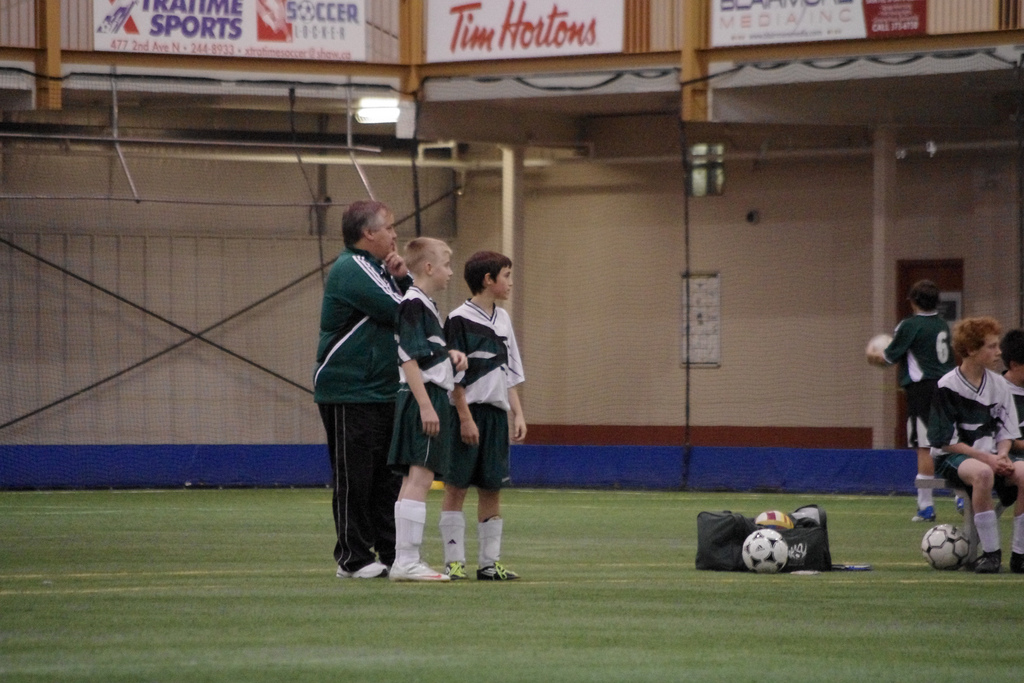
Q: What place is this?
A: It is a field.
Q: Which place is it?
A: It is a field.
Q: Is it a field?
A: Yes, it is a field.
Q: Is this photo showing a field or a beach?
A: It is showing a field.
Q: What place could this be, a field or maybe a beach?
A: It is a field.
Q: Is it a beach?
A: No, it is a field.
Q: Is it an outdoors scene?
A: Yes, it is outdoors.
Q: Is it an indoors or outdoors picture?
A: It is outdoors.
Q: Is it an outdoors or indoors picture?
A: It is outdoors.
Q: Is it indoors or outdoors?
A: It is outdoors.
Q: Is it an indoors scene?
A: No, it is outdoors.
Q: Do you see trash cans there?
A: No, there are no trash cans.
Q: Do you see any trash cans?
A: No, there are no trash cans.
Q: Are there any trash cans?
A: No, there are no trash cans.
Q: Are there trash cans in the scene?
A: No, there are no trash cans.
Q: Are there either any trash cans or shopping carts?
A: No, there are no trash cans or shopping carts.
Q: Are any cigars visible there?
A: No, there are no cigars.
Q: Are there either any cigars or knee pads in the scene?
A: No, there are no cigars or knee pads.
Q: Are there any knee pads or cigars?
A: No, there are no cigars or knee pads.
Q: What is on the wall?
A: The poster is on the wall.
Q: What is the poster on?
A: The poster is on the wall.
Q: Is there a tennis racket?
A: No, there are no rackets.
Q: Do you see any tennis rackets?
A: No, there are no tennis rackets.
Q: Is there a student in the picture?
A: No, there are no students.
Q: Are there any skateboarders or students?
A: No, there are no students or skateboarders.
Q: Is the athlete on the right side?
A: Yes, the athlete is on the right of the image.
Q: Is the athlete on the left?
A: No, the athlete is on the right of the image.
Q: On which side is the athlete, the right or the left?
A: The athlete is on the right of the image.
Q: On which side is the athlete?
A: The athlete is on the right of the image.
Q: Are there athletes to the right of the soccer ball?
A: Yes, there is an athlete to the right of the soccer ball.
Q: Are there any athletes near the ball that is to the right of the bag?
A: Yes, there is an athlete near the ball.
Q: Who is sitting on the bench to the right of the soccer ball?
A: The athlete is sitting on the bench.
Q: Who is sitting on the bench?
A: The athlete is sitting on the bench.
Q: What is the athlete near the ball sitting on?
A: The athlete is sitting on the bench.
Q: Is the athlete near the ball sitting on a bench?
A: Yes, the athlete is sitting on a bench.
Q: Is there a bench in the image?
A: Yes, there is a bench.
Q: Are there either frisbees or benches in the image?
A: Yes, there is a bench.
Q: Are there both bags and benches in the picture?
A: Yes, there are both a bench and a bag.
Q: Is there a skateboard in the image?
A: No, there are no skateboards.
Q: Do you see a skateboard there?
A: No, there are no skateboards.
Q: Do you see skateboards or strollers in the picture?
A: No, there are no skateboards or strollers.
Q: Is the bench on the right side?
A: Yes, the bench is on the right of the image.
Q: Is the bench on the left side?
A: No, the bench is on the right of the image.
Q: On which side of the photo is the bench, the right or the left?
A: The bench is on the right of the image.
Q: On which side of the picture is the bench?
A: The bench is on the right of the image.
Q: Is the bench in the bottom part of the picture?
A: Yes, the bench is in the bottom of the image.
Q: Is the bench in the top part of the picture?
A: No, the bench is in the bottom of the image.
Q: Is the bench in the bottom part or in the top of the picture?
A: The bench is in the bottom of the image.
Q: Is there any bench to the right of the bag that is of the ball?
A: Yes, there is a bench to the right of the bag.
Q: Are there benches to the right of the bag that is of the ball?
A: Yes, there is a bench to the right of the bag.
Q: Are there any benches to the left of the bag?
A: No, the bench is to the right of the bag.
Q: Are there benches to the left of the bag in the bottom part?
A: No, the bench is to the right of the bag.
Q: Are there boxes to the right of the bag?
A: No, there is a bench to the right of the bag.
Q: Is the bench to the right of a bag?
A: Yes, the bench is to the right of a bag.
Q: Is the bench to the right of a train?
A: No, the bench is to the right of a bag.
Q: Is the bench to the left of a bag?
A: No, the bench is to the right of a bag.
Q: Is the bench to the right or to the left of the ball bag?
A: The bench is to the right of the bag.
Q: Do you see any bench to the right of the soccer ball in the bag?
A: Yes, there is a bench to the right of the soccer ball.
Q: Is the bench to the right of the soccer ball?
A: Yes, the bench is to the right of the soccer ball.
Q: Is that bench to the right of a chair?
A: No, the bench is to the right of the soccer ball.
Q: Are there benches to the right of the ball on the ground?
A: Yes, there is a bench to the right of the ball.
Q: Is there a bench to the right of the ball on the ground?
A: Yes, there is a bench to the right of the ball.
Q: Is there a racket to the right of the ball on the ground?
A: No, there is a bench to the right of the ball.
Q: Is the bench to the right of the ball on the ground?
A: Yes, the bench is to the right of the ball.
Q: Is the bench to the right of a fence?
A: No, the bench is to the right of the ball.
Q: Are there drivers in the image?
A: No, there are no drivers.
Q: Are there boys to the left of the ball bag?
A: Yes, there is a boy to the left of the bag.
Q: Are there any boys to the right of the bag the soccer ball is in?
A: No, the boy is to the left of the bag.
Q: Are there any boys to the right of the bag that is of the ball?
A: No, the boy is to the left of the bag.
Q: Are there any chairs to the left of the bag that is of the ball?
A: No, there is a boy to the left of the bag.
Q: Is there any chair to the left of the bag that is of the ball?
A: No, there is a boy to the left of the bag.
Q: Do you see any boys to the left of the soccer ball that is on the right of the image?
A: Yes, there is a boy to the left of the soccer ball.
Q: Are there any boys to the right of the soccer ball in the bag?
A: No, the boy is to the left of the soccer ball.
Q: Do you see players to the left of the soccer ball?
A: No, there is a boy to the left of the soccer ball.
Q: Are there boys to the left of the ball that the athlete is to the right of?
A: Yes, there is a boy to the left of the ball.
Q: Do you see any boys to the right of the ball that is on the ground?
A: No, the boy is to the left of the ball.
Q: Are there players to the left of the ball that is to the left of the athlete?
A: No, there is a boy to the left of the ball.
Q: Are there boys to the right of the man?
A: Yes, there is a boy to the right of the man.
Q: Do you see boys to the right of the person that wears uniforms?
A: Yes, there is a boy to the right of the man.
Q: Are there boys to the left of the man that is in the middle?
A: No, the boy is to the right of the man.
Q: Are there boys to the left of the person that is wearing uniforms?
A: No, the boy is to the right of the man.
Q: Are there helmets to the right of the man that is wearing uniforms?
A: No, there is a boy to the right of the man.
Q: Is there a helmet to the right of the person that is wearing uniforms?
A: No, there is a boy to the right of the man.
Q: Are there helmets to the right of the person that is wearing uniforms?
A: No, there is a boy to the right of the man.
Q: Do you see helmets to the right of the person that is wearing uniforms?
A: No, there is a boy to the right of the man.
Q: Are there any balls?
A: Yes, there is a ball.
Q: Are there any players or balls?
A: Yes, there is a ball.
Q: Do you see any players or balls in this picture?
A: Yes, there is a ball.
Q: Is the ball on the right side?
A: Yes, the ball is on the right of the image.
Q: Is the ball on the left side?
A: No, the ball is on the right of the image.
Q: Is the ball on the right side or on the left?
A: The ball is on the right of the image.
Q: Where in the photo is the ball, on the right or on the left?
A: The ball is on the right of the image.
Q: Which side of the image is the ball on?
A: The ball is on the right of the image.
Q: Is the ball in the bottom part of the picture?
A: Yes, the ball is in the bottom of the image.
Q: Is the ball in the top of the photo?
A: No, the ball is in the bottom of the image.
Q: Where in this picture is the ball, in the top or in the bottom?
A: The ball is in the bottom of the image.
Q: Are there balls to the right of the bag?
A: Yes, there is a ball to the right of the bag.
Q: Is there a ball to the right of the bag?
A: Yes, there is a ball to the right of the bag.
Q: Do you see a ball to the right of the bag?
A: Yes, there is a ball to the right of the bag.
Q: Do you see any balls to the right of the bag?
A: Yes, there is a ball to the right of the bag.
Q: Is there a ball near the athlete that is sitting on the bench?
A: Yes, there is a ball near the athlete.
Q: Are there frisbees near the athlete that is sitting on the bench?
A: No, there is a ball near the athlete.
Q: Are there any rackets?
A: No, there are no rackets.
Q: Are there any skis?
A: No, there are no skis.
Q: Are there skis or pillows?
A: No, there are no skis or pillows.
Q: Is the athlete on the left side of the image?
A: No, the athlete is on the right of the image.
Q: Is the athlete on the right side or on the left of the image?
A: The athlete is on the right of the image.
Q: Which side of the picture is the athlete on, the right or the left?
A: The athlete is on the right of the image.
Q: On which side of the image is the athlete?
A: The athlete is on the right of the image.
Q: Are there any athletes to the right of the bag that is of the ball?
A: Yes, there is an athlete to the right of the bag.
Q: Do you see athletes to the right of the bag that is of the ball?
A: Yes, there is an athlete to the right of the bag.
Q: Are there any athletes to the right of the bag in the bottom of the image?
A: Yes, there is an athlete to the right of the bag.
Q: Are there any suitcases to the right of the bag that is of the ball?
A: No, there is an athlete to the right of the bag.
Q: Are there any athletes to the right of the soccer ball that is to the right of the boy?
A: Yes, there is an athlete to the right of the soccer ball.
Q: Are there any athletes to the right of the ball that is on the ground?
A: Yes, there is an athlete to the right of the ball.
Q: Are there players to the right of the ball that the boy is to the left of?
A: No, there is an athlete to the right of the ball.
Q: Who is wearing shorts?
A: The athlete is wearing shorts.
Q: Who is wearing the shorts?
A: The athlete is wearing shorts.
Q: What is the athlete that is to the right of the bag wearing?
A: The athlete is wearing shorts.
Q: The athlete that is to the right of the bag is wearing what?
A: The athlete is wearing shorts.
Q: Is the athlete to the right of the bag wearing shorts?
A: Yes, the athlete is wearing shorts.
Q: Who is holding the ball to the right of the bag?
A: The athlete is holding the ball.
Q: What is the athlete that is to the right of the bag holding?
A: The athlete is holding the ball.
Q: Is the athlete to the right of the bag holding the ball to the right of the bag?
A: Yes, the athlete is holding the ball.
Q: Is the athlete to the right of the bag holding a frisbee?
A: No, the athlete is holding the ball.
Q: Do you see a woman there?
A: No, there are no women.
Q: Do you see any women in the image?
A: No, there are no women.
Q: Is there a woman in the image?
A: No, there are no women.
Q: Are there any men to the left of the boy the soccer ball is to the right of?
A: Yes, there is a man to the left of the boy.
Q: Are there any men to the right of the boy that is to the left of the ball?
A: No, the man is to the left of the boy.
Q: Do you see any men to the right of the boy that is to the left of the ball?
A: No, the man is to the left of the boy.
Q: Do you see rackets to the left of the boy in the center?
A: No, there is a man to the left of the boy.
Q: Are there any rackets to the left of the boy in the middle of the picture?
A: No, there is a man to the left of the boy.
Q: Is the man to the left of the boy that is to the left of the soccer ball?
A: Yes, the man is to the left of the boy.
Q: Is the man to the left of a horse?
A: No, the man is to the left of the boy.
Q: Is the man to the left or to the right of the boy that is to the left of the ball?
A: The man is to the left of the boy.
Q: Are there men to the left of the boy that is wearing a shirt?
A: Yes, there is a man to the left of the boy.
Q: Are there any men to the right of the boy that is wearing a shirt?
A: No, the man is to the left of the boy.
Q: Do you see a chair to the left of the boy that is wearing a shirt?
A: No, there is a man to the left of the boy.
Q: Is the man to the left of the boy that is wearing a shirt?
A: Yes, the man is to the left of the boy.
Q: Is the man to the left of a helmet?
A: No, the man is to the left of the boy.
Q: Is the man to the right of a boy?
A: No, the man is to the left of a boy.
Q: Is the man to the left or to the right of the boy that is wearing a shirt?
A: The man is to the left of the boy.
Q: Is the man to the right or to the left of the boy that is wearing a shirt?
A: The man is to the left of the boy.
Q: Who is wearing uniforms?
A: The man is wearing uniforms.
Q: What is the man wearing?
A: The man is wearing uniforms.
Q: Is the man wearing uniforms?
A: Yes, the man is wearing uniforms.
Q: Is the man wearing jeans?
A: No, the man is wearing uniforms.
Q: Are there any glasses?
A: No, there are no glasses.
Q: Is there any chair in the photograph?
A: No, there are no chairs.